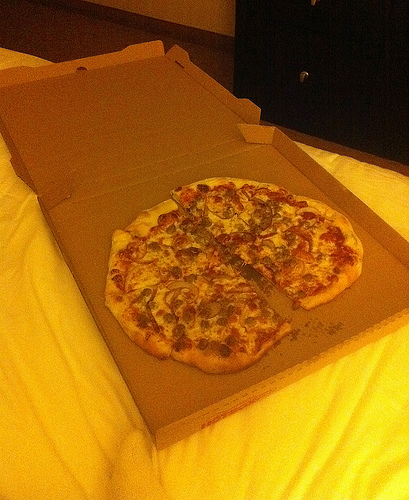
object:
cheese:
[144, 237, 219, 319]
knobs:
[296, 1, 314, 89]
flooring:
[0, 0, 235, 102]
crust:
[113, 194, 177, 222]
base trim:
[91, 0, 247, 41]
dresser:
[234, 1, 408, 174]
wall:
[85, 0, 236, 43]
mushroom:
[202, 300, 223, 317]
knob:
[292, 65, 318, 95]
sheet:
[0, 48, 408, 498]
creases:
[276, 334, 403, 496]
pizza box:
[1, 35, 409, 459]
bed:
[0, 38, 409, 500]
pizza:
[101, 172, 363, 378]